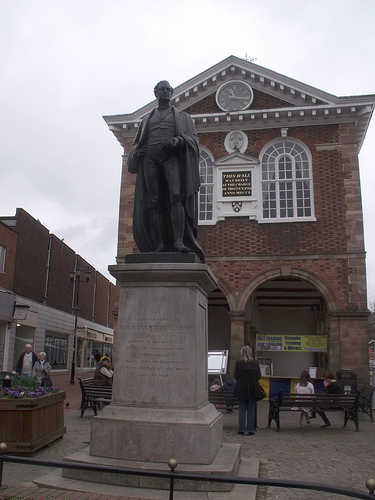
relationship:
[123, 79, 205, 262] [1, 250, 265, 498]
statue standing on a pedestal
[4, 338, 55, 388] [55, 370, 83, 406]
man walking down sidewalk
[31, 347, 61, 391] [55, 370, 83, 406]
woman walking down sidewalk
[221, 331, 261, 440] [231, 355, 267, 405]
woman dressed in black jacket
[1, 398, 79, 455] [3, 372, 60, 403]
container holding flowers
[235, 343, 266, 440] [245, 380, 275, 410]
woman wearing black purse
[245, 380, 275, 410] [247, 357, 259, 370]
black purse over shoulder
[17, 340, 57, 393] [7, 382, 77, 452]
couple walking towards bed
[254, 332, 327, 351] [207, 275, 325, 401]
banner under alcove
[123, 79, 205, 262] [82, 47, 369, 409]
statue in front of building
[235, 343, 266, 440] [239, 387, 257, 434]
woman wears jeans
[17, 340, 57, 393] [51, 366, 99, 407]
couple walking on street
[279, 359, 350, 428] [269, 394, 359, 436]
couple sitting on a bench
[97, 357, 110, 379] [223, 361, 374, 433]
people sits on a bench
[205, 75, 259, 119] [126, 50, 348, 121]
clock under roof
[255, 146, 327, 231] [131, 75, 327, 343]
window on building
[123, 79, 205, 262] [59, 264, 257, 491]
statue on a monument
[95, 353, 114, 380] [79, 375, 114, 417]
people sit on bench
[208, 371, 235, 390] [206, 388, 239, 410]
people sit on bench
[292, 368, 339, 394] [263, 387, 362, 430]
people sit on bench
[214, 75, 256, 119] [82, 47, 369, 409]
clock on building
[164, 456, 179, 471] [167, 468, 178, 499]
top of post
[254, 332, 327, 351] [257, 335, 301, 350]
banner with writing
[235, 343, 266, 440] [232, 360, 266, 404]
woman in black jacket